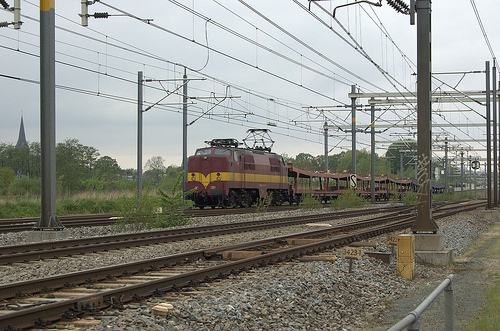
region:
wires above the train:
[173, 37, 297, 109]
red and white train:
[186, 136, 283, 199]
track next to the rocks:
[235, 218, 321, 283]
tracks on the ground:
[97, 207, 276, 309]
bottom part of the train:
[217, 186, 288, 217]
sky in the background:
[96, 105, 123, 125]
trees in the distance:
[62, 134, 115, 176]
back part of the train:
[369, 171, 413, 212]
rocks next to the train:
[244, 275, 311, 323]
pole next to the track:
[388, 14, 455, 219]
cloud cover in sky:
[0, 0, 499, 167]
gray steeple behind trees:
[2, 109, 39, 179]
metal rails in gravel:
[0, 229, 379, 328]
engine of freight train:
[184, 142, 416, 205]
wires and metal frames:
[54, 4, 495, 136]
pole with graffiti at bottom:
[408, 2, 438, 234]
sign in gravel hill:
[295, 241, 392, 309]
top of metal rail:
[376, 272, 460, 329]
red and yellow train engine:
[185, 145, 287, 209]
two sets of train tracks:
[0, 231, 345, 328]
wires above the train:
[182, 9, 333, 169]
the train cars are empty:
[291, 157, 418, 200]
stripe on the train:
[190, 167, 292, 187]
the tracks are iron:
[107, 225, 299, 287]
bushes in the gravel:
[94, 187, 220, 242]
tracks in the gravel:
[126, 239, 320, 309]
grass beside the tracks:
[57, 177, 188, 229]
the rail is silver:
[396, 267, 477, 325]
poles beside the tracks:
[36, 51, 204, 223]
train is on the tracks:
[179, 118, 334, 215]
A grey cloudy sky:
[0, 0, 499, 172]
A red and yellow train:
[184, 139, 451, 208]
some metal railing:
[388, 272, 453, 329]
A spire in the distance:
[12, 110, 34, 152]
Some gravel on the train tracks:
[0, 200, 499, 330]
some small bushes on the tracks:
[111, 169, 200, 234]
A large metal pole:
[409, 0, 434, 232]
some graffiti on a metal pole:
[414, 153, 429, 200]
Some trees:
[1, 136, 133, 192]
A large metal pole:
[33, 0, 60, 231]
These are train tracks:
[61, 180, 284, 328]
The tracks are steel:
[84, 220, 144, 318]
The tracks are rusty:
[53, 245, 140, 304]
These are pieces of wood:
[51, 275, 138, 300]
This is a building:
[22, 107, 27, 170]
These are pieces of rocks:
[232, 285, 278, 320]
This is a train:
[170, 92, 280, 194]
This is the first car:
[180, 100, 350, 211]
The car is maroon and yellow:
[212, 160, 337, 295]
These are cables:
[235, 49, 377, 109]